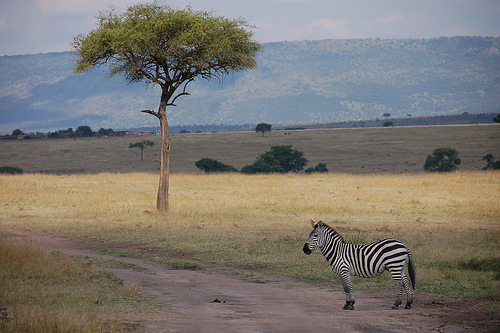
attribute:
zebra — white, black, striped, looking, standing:
[296, 214, 419, 313]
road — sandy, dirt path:
[12, 203, 474, 331]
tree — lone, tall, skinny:
[63, 0, 259, 217]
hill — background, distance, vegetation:
[2, 36, 494, 155]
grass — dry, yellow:
[202, 188, 304, 228]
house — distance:
[72, 119, 135, 149]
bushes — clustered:
[192, 140, 334, 183]